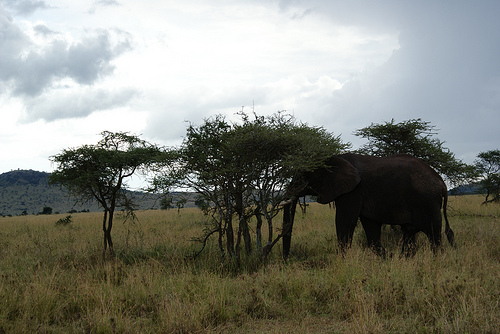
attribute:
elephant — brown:
[328, 171, 445, 220]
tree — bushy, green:
[207, 132, 246, 257]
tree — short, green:
[58, 137, 158, 272]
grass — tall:
[467, 222, 492, 246]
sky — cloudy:
[143, 12, 406, 90]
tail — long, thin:
[447, 202, 448, 224]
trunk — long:
[287, 207, 291, 251]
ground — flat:
[255, 318, 331, 333]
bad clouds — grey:
[0, 3, 401, 195]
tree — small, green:
[163, 118, 340, 268]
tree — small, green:
[52, 130, 174, 259]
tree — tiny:
[59, 110, 197, 262]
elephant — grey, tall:
[281, 152, 458, 262]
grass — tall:
[321, 246, 450, 268]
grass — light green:
[111, 257, 236, 332]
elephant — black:
[277, 145, 464, 265]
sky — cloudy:
[20, 3, 477, 131]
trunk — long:
[258, 185, 315, 272]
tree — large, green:
[55, 130, 186, 254]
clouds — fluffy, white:
[220, 13, 407, 103]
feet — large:
[333, 244, 445, 259]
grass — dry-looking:
[0, 195, 497, 332]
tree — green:
[56, 130, 173, 278]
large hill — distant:
[4, 155, 148, 224]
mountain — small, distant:
[0, 168, 499, 217]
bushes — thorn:
[43, 100, 483, 265]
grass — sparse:
[0, 168, 498, 330]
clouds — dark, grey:
[1, 2, 498, 189]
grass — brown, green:
[1, 210, 498, 330]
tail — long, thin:
[440, 185, 453, 251]